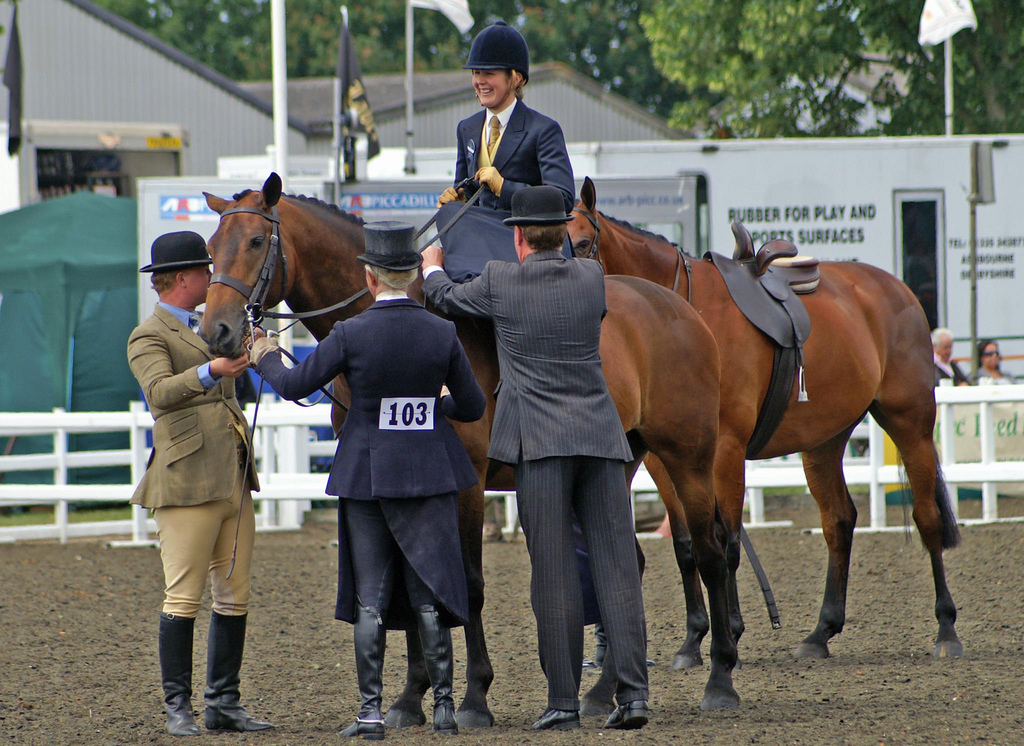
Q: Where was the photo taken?
A: In an Equestrian show place.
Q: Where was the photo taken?
A: At a horse show.